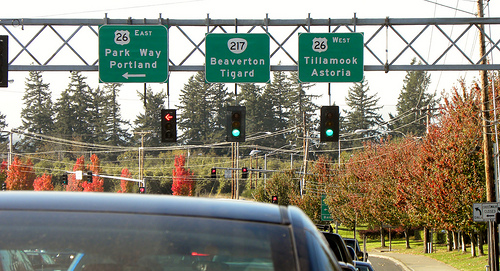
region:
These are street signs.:
[70, 20, 384, 120]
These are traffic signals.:
[143, 91, 412, 156]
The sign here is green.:
[310, 117, 341, 150]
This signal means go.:
[316, 123, 345, 142]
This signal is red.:
[151, 103, 203, 153]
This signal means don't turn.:
[136, 106, 203, 160]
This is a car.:
[5, 175, 302, 267]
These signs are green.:
[101, 19, 379, 81]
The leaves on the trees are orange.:
[321, 144, 477, 216]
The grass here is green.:
[422, 244, 467, 269]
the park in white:
[103, 47, 131, 57]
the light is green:
[228, 128, 240, 138]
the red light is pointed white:
[163, 112, 175, 122]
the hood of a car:
[0, 186, 337, 269]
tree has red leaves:
[172, 152, 191, 196]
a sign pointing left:
[474, 201, 484, 223]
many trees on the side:
[319, 84, 499, 256]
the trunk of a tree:
[421, 227, 430, 252]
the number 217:
[227, 37, 247, 53]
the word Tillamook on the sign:
[302, 53, 359, 68]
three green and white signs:
[87, 18, 370, 83]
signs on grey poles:
[95, 15, 375, 105]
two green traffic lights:
[211, 88, 380, 135]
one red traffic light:
[146, 100, 201, 154]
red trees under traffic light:
[5, 151, 207, 193]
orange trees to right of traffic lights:
[348, 144, 499, 227]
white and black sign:
[458, 193, 498, 232]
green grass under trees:
[342, 209, 499, 268]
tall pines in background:
[20, 70, 432, 144]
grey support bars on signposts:
[8, 23, 481, 77]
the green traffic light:
[326, 128, 333, 135]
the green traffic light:
[232, 129, 239, 136]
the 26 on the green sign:
[115, 31, 128, 41]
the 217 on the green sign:
[229, 40, 245, 50]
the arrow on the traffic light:
[164, 112, 173, 119]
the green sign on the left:
[98, 24, 168, 82]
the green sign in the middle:
[204, 34, 269, 82]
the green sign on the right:
[298, 33, 363, 80]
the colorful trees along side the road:
[1, 57, 499, 254]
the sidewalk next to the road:
[361, 246, 461, 269]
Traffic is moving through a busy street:
[15, 22, 475, 260]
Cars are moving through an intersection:
[21, 26, 462, 251]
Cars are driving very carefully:
[11, 60, 482, 270]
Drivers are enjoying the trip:
[0, 78, 486, 268]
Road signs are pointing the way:
[25, 3, 443, 266]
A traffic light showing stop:
[160, 107, 175, 142]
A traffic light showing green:
[226, 103, 243, 144]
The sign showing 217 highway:
[205, 32, 266, 83]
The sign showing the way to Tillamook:
[299, 33, 362, 81]